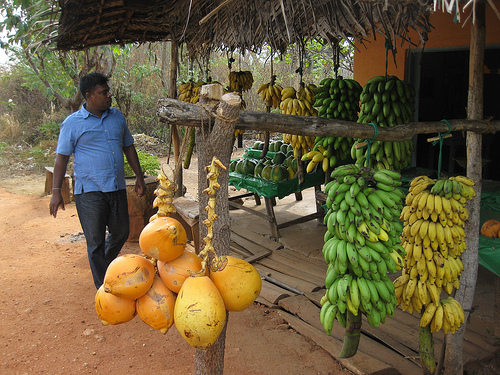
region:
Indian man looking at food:
[45, 64, 157, 301]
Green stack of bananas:
[312, 156, 403, 327]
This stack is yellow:
[402, 169, 468, 339]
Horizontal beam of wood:
[148, 84, 496, 149]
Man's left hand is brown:
[41, 185, 68, 217]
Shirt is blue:
[60, 103, 134, 201]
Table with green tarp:
[238, 145, 327, 204]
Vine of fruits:
[196, 149, 233, 264]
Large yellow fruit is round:
[178, 268, 230, 347]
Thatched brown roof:
[55, 3, 422, 43]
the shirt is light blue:
[59, 122, 135, 178]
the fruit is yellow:
[174, 272, 235, 353]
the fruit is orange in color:
[103, 255, 157, 299]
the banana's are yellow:
[414, 217, 469, 262]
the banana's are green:
[330, 245, 382, 275]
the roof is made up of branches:
[230, 12, 311, 30]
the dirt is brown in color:
[13, 280, 78, 326]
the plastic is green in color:
[239, 170, 278, 202]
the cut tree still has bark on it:
[183, 75, 268, 212]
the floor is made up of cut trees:
[247, 241, 317, 297]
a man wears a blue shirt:
[42, 62, 157, 302]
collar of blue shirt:
[69, 104, 114, 128]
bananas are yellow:
[399, 121, 479, 341]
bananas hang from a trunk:
[399, 114, 499, 344]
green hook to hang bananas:
[428, 107, 457, 176]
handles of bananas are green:
[311, 136, 410, 336]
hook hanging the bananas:
[357, 116, 382, 168]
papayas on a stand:
[230, 133, 299, 197]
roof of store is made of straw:
[39, 0, 486, 66]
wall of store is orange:
[351, 14, 485, 91]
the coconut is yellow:
[85, 243, 315, 358]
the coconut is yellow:
[108, 240, 253, 333]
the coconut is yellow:
[68, 195, 231, 320]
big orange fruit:
[97, 202, 261, 356]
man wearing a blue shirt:
[20, 60, 149, 190]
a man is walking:
[11, 53, 166, 305]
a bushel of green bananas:
[302, 145, 410, 342]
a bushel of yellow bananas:
[394, 150, 464, 350]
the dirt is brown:
[12, 236, 169, 372]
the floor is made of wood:
[235, 240, 315, 308]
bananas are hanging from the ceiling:
[247, 5, 345, 149]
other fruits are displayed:
[215, 128, 301, 202]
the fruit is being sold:
[40, 40, 465, 333]